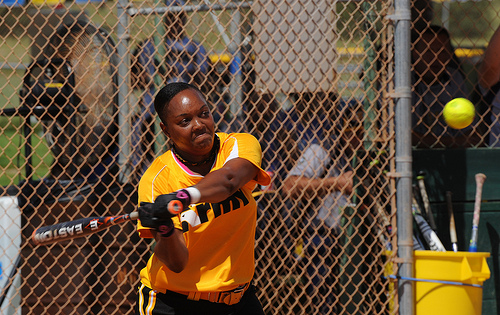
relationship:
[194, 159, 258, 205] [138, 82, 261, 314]
arm of girl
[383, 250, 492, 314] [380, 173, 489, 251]
bucket contains bats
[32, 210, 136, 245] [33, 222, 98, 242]
bat has letters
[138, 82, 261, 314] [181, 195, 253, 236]
girl has letters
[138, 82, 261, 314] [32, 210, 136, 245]
girl holding bat